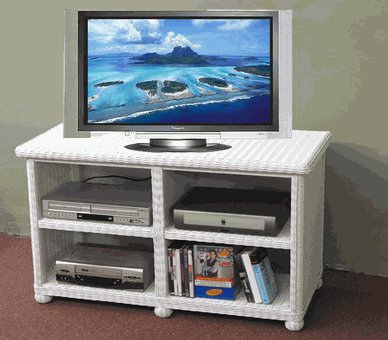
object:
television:
[60, 8, 294, 154]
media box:
[170, 185, 291, 238]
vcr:
[53, 241, 156, 293]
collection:
[247, 247, 278, 306]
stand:
[13, 120, 331, 333]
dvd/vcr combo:
[40, 180, 151, 226]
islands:
[84, 45, 271, 127]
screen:
[86, 17, 275, 127]